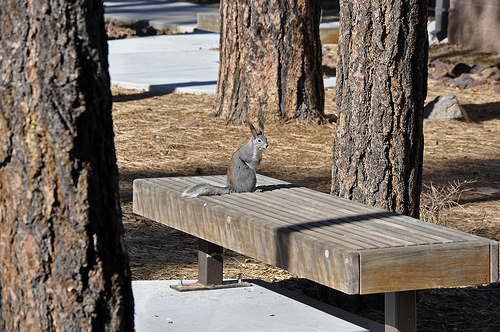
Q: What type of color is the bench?
A: Gray.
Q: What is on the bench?
A: Squirrel.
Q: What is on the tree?
A: Bark.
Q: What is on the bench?
A: Gray rabbit.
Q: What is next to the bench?
A: Tree.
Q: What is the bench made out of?
A: Wood.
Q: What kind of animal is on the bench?
A: Squirrel.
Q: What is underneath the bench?
A: Concrete.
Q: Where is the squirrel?
A: On the bench.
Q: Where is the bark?
A: On the trees.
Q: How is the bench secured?
A: Bolts.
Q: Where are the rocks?
A: Behind the trees.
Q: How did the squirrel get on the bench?
A: Jumped.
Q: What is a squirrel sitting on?
A: A bench.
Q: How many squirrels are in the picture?
A: One.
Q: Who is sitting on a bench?
A: A squirrel.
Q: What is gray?
A: Squirrel.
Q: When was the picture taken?
A: During the day.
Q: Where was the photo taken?
A: At a park.